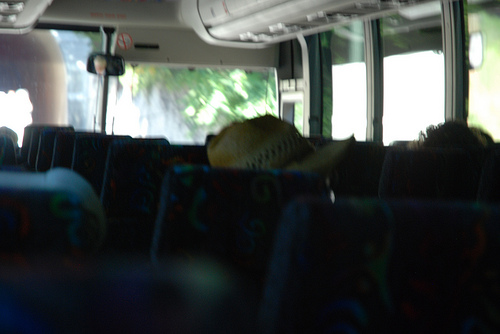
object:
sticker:
[115, 33, 134, 50]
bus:
[1, 1, 500, 331]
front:
[1, 1, 282, 138]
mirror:
[86, 52, 126, 75]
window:
[0, 19, 278, 149]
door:
[278, 78, 306, 138]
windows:
[365, 0, 449, 149]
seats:
[0, 164, 100, 268]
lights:
[241, 31, 265, 43]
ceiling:
[3, 0, 497, 50]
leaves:
[179, 65, 218, 100]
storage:
[177, 0, 419, 49]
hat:
[205, 114, 356, 179]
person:
[200, 110, 360, 207]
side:
[254, 0, 499, 179]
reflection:
[94, 56, 108, 75]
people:
[201, 115, 494, 200]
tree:
[118, 52, 275, 145]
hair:
[416, 115, 492, 151]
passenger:
[415, 117, 487, 158]